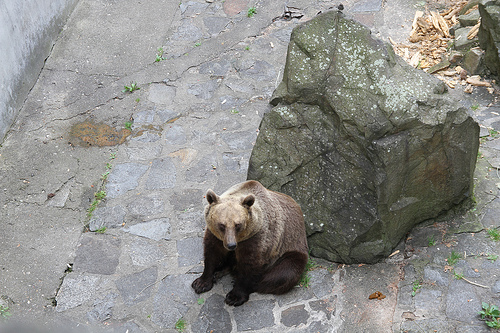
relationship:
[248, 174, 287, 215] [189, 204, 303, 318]
back of bear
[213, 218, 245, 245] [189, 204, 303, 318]
muzzle of bear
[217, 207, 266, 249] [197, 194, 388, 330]
head of bear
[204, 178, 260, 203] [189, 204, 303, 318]
ears of bear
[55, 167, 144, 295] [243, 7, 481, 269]
cracks in rock